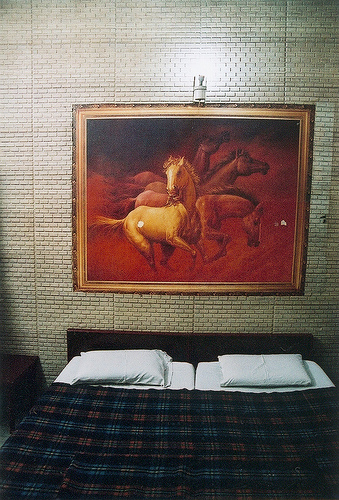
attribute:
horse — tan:
[89, 152, 209, 274]